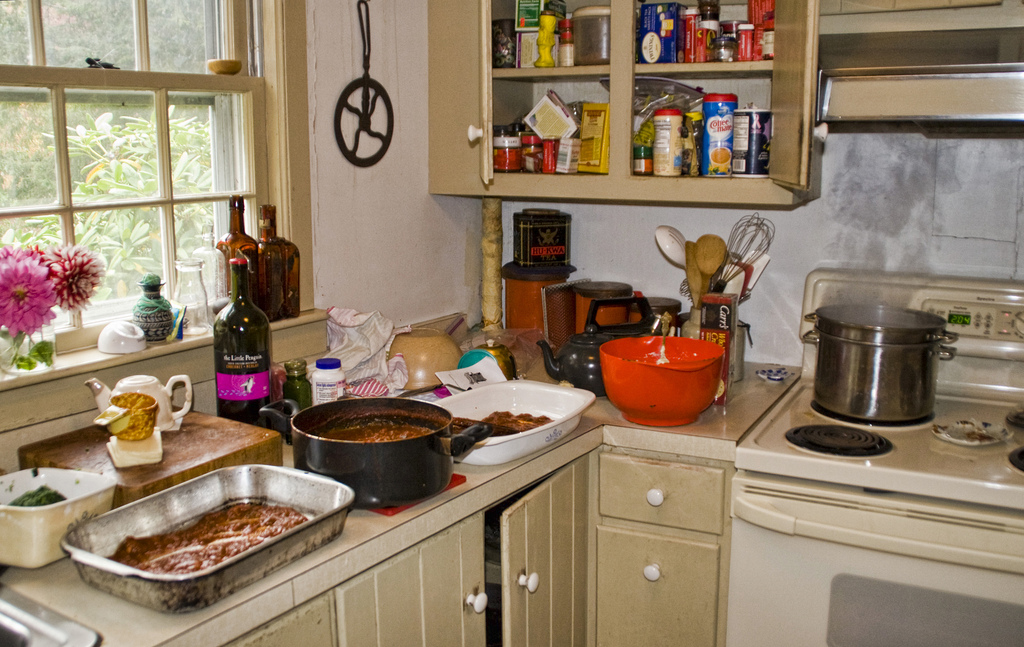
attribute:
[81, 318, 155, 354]
timer — kitchen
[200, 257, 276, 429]
bottle — wine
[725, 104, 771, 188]
container — salt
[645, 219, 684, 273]
spoon — white, cooking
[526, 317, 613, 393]
pot — black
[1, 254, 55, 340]
flower — large, pink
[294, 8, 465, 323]
wall — white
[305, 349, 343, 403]
bottle — blue, white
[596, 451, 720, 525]
drawer — small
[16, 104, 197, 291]
leaves — green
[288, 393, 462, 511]
pot — black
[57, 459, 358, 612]
dish — silver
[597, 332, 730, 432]
bowl — orange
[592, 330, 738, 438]
red bowl — large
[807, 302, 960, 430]
pot — large, gray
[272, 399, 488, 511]
pot — large , black 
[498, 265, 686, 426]
teapot — small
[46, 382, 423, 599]
gravy pan — long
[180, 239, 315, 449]
whine bottle — tall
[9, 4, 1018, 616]
kitchen — big